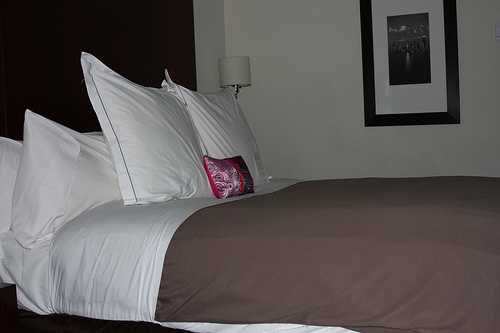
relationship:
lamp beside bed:
[206, 55, 258, 107] [16, 172, 498, 332]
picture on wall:
[343, 6, 478, 140] [221, 1, 499, 183]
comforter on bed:
[186, 176, 486, 330] [4, 22, 488, 324]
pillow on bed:
[198, 152, 254, 201] [16, 172, 498, 332]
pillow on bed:
[161, 70, 266, 183] [16, 172, 498, 332]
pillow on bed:
[79, 49, 215, 210] [16, 172, 498, 332]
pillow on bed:
[9, 107, 126, 246] [16, 172, 498, 332]